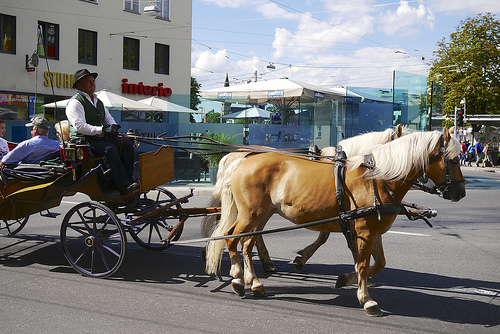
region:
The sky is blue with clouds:
[285, 10, 390, 110]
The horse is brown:
[251, 151, 373, 213]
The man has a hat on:
[54, 62, 149, 169]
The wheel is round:
[34, 187, 150, 300]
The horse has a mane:
[347, 127, 498, 221]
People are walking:
[449, 118, 496, 190]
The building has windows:
[5, 10, 165, 125]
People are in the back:
[0, 101, 115, 198]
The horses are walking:
[216, 250, 402, 330]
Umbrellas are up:
[80, 65, 207, 141]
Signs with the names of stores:
[41, 69, 174, 102]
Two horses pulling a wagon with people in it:
[3, 68, 469, 318]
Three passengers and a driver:
[1, 69, 142, 199]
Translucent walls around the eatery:
[2, 69, 441, 186]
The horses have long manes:
[313, 122, 463, 183]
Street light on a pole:
[452, 104, 466, 132]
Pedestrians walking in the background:
[457, 137, 496, 169]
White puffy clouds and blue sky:
[191, 1, 499, 99]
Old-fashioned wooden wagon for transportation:
[0, 143, 195, 280]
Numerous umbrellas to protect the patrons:
[35, 74, 379, 120]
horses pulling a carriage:
[14, 54, 485, 328]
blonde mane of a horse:
[366, 127, 437, 177]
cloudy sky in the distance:
[207, 16, 413, 79]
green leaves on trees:
[433, 17, 497, 107]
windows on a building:
[118, 33, 179, 79]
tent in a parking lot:
[206, 70, 353, 113]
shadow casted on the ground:
[388, 261, 491, 331]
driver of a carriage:
[56, 65, 156, 182]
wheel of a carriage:
[56, 194, 136, 278]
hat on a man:
[17, 105, 56, 128]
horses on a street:
[201, 119, 473, 323]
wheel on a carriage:
[54, 197, 133, 284]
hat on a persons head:
[67, 65, 104, 92]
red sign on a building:
[114, 74, 177, 101]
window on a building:
[147, 37, 176, 81]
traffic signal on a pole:
[453, 103, 468, 131]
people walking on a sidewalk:
[471, 132, 498, 172]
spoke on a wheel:
[83, 245, 98, 276]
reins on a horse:
[111, 125, 338, 167]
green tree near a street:
[418, 6, 498, 119]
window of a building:
[153, 2, 183, 16]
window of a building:
[139, 38, 179, 85]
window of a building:
[130, 32, 154, 62]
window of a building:
[72, 22, 123, 63]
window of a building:
[33, 19, 84, 53]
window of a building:
[0, 9, 40, 54]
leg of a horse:
[205, 208, 239, 303]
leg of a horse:
[226, 215, 263, 297]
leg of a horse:
[275, 201, 332, 273]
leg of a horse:
[322, 218, 392, 303]